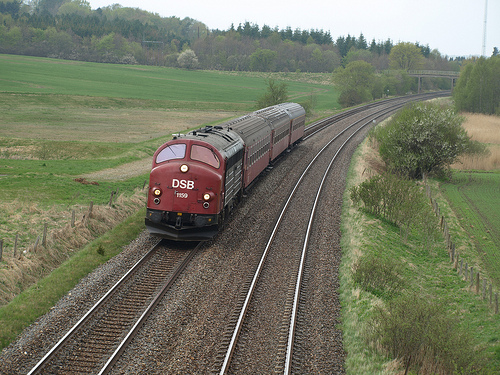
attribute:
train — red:
[137, 99, 310, 253]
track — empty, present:
[31, 235, 195, 375]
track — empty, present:
[213, 119, 389, 371]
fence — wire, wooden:
[8, 184, 133, 278]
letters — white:
[170, 176, 197, 193]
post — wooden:
[66, 208, 78, 231]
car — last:
[282, 97, 310, 148]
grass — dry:
[41, 224, 109, 263]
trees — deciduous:
[231, 20, 372, 51]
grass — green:
[21, 163, 93, 203]